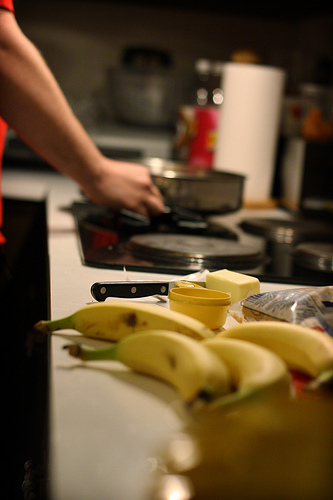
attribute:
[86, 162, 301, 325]
stove — black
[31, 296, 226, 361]
bananas — brown and yellow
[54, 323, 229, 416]
banana — brown, yellow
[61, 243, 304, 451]
table — white